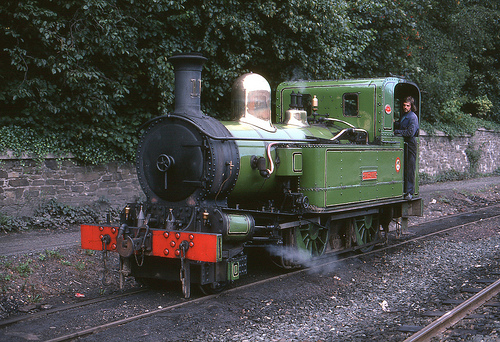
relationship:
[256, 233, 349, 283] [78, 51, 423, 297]
smoke emanating from engine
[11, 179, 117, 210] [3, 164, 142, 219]
stone on wall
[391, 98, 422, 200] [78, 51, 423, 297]
man in engine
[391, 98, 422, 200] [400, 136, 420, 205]
man has jeans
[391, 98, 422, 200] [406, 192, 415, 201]
man has shoes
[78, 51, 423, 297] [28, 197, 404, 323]
engine on tracks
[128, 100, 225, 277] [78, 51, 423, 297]
front of engine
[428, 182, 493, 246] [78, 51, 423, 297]
track behind engine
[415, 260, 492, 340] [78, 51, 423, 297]
track beside engine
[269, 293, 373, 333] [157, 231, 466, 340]
ballast on ground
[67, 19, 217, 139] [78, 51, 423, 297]
leaves next to engine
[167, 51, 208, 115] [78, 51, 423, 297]
smoke stack of engine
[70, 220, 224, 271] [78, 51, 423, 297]
bumper of engine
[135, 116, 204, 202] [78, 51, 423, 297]
circle of engine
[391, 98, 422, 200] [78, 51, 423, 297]
man standing in engine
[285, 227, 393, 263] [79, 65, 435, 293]
wheels of train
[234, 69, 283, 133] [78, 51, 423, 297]
part of engine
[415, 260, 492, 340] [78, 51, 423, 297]
track of engine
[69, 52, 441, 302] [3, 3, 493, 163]
trees behind train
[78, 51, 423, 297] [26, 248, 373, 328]
engine on tracks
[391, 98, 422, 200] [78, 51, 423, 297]
man on engine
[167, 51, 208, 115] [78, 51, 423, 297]
smoke stack of a engine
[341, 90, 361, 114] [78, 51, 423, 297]
window in a engine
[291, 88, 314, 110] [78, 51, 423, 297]
window in a engine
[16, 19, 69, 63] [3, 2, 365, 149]
leaves of a tree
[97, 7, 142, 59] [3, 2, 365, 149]
leaves of a tree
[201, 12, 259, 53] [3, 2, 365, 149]
leaves of a tree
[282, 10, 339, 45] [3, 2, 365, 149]
leaves of a tree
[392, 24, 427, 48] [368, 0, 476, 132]
leaves of a tree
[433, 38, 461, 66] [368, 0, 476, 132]
leaves of a tree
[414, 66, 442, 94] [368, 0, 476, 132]
leaves of a tree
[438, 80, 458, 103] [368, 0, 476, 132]
leaves of a tree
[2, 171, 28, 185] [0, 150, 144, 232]
brick of a brick wall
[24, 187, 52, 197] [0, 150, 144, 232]
brick of a brick wall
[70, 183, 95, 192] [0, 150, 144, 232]
brick of a brick wall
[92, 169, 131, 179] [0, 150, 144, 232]
brick of a brick wall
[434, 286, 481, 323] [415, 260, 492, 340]
track of a track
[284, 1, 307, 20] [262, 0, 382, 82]
leaves of a tree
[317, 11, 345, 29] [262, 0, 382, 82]
leaves of a tree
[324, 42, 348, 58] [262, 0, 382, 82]
leaves of a tree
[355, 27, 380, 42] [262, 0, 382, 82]
leaves of a tree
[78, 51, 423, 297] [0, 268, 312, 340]
engine on track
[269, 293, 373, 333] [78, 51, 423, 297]
ballast near engine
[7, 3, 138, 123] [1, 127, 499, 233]
tree behind fence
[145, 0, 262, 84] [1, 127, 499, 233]
tree behind fence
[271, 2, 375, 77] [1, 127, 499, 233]
tree behind fence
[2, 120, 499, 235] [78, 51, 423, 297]
wall behind engine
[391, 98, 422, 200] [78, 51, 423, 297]
man stands on engine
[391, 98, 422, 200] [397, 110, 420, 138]
man has shirt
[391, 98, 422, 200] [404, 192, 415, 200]
man has shoes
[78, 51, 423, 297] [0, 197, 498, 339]
engine on tracks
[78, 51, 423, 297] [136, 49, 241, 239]
engine has front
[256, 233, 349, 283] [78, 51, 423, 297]
smoke out of engine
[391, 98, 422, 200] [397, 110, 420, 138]
man wearing shirt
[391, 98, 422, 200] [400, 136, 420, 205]
man wearing jeans